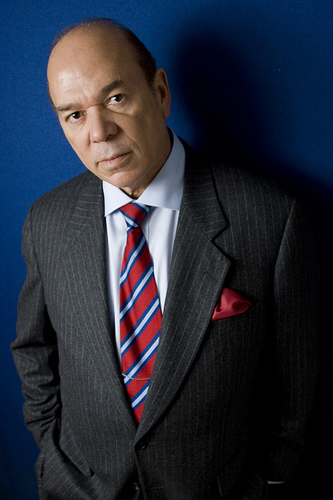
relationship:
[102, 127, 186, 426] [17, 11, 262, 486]
shirt on man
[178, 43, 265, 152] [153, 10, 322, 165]
shadow on background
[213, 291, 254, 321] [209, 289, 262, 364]
object in pocket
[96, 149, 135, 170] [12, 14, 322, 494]
mouth on man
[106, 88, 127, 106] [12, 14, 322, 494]
eye on man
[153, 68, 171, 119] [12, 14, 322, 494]
ear on man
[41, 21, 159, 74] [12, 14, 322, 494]
head on man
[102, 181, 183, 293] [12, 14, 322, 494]
shirt on man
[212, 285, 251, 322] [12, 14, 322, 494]
handkerchief on man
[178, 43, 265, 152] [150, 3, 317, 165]
shadow on wall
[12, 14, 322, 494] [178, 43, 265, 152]
man with shadow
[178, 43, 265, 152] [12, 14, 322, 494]
shadow of man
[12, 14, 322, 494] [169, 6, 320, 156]
man by wall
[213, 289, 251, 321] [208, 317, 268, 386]
handkerchief in pocket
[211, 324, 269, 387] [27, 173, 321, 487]
pocket on jacket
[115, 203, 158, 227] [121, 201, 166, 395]
knot on tie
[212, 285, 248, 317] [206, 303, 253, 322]
handkerchief in pocket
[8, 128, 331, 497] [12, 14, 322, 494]
jacket on man